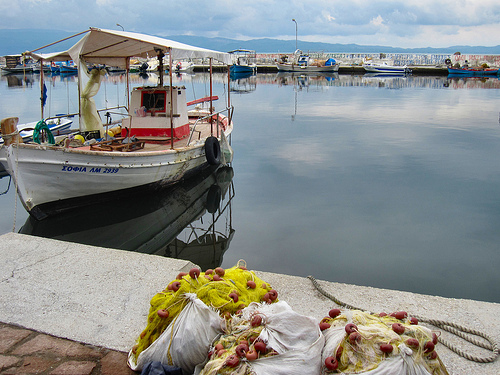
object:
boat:
[0, 25, 237, 223]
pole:
[209, 58, 214, 138]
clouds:
[0, 0, 500, 50]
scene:
[0, 26, 500, 375]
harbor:
[0, 229, 500, 374]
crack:
[0, 240, 70, 286]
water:
[0, 70, 500, 301]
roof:
[25, 26, 232, 70]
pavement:
[0, 231, 500, 375]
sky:
[0, 0, 500, 49]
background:
[0, 0, 500, 375]